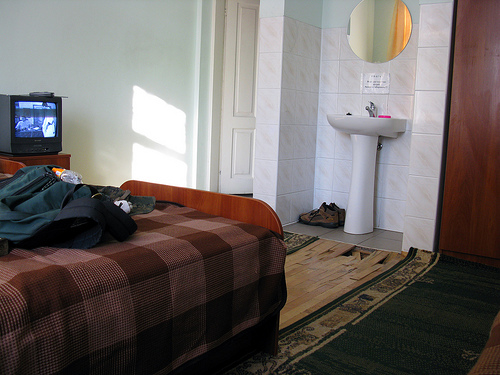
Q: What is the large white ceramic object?
A: A sink.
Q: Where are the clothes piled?
A: On the bed.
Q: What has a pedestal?
A: The sink.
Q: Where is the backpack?
A: On the bed.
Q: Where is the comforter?
A: On the bed.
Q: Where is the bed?
A: A bedroom.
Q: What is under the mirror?
A: A sink.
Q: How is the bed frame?
A: With wood.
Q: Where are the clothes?
A: On the bed.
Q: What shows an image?
A: The TV.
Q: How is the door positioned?
A: Open.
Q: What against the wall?
A: Sink.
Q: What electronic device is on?
A: Tv.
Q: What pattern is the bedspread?
A: Plaid.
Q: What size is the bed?
A: Twin.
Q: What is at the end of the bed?
A: Footboard.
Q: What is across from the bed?
A: A sink.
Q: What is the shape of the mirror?
A: Circle.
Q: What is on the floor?
A: A rug.